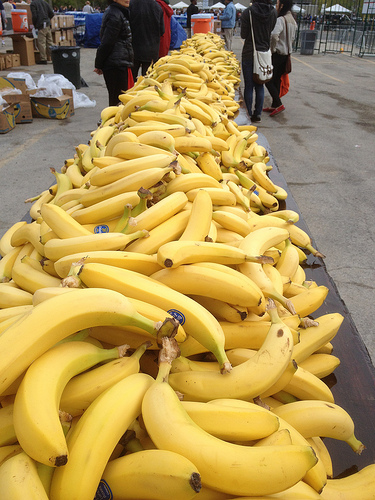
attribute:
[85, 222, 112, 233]
stickers — blue 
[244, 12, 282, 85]
shoulder bag — white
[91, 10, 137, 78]
coat — black 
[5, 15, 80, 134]
boxes — cardboard 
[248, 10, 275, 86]
bag — white 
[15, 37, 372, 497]
table — full , wooden , dark, long 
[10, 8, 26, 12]
lid — white 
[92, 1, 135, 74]
jacket — black 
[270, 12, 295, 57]
shirt — gray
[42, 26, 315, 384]
bananas — pile, yellow, ripe, attractive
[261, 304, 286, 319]
stem — Green 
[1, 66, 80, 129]
boxes — Brown 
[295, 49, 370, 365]
ground — wet, gray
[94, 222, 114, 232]
stickers — Blue , little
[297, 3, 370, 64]
fence — black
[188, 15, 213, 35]
cooler — Large , orange 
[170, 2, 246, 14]
tents — White 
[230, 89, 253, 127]
table — wooden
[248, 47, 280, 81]
bag — brown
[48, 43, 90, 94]
can — black